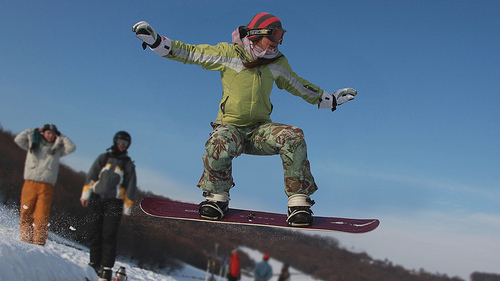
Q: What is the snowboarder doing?
A: A stunt.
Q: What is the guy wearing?
A: Green jacket.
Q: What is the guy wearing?
A: Gloves.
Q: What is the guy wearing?
A: Green pants.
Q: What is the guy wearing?
A: Black shoes.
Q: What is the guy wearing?
A: Ski goggles.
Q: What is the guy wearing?
A: Camouflage pants.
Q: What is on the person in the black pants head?
A: Helmet.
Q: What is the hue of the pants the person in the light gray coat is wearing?
A: Orange.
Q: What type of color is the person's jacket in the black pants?
A: Gray, white and Yellow.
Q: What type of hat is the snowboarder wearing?
A: Striped.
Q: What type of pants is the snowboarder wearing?
A: Green and brown.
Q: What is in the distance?
A: Trees.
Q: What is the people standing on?
A: Snow.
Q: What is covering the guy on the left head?
A: A hat.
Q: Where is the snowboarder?
A: In the air.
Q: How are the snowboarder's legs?
A: Bent.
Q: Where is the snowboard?
A: On the boarder.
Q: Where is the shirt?
A: On boarder.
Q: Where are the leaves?
A: On the trees.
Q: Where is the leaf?
A: On the tree.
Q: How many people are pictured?
A: Six.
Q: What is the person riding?
A: A snowboard.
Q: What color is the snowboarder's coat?
A: Green.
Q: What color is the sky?
A: Blue.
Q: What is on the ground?
A: Snow.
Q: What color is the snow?
A: White.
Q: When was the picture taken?
A: Daytime.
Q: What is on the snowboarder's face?
A: Goggles.